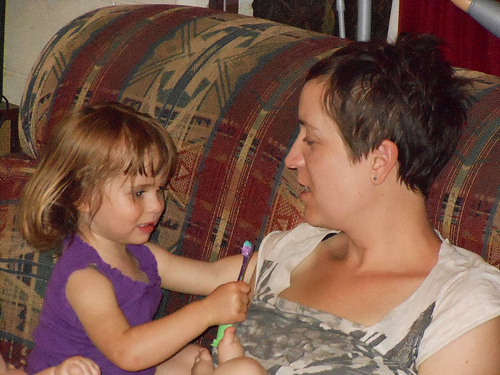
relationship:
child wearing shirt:
[15, 93, 271, 371] [20, 233, 167, 372]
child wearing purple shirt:
[15, 93, 271, 371] [31, 241, 159, 372]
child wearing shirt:
[17, 100, 257, 375] [20, 233, 167, 372]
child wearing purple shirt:
[17, 100, 257, 375] [22, 232, 171, 374]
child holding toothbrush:
[15, 93, 271, 371] [192, 236, 287, 326]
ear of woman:
[371, 138, 403, 198] [205, 37, 499, 374]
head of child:
[16, 103, 173, 249] [17, 100, 257, 375]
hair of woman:
[306, 27, 472, 191] [205, 37, 499, 374]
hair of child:
[22, 92, 194, 243] [17, 100, 257, 375]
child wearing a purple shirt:
[17, 100, 257, 375] [27, 233, 162, 375]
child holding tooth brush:
[17, 100, 257, 375] [212, 233, 253, 350]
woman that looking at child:
[205, 37, 499, 374] [15, 100, 248, 373]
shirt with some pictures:
[216, 222, 498, 372] [233, 299, 437, 372]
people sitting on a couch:
[2, 24, 498, 373] [2, 1, 496, 374]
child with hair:
[17, 100, 257, 375] [14, 93, 182, 262]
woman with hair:
[205, 37, 499, 374] [306, 32, 477, 200]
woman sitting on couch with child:
[212, 32, 500, 375] [21, 104, 210, 327]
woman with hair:
[205, 37, 499, 374] [312, 36, 462, 194]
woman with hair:
[212, 32, 500, 375] [285, 13, 484, 207]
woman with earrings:
[212, 32, 500, 375] [371, 167, 385, 194]